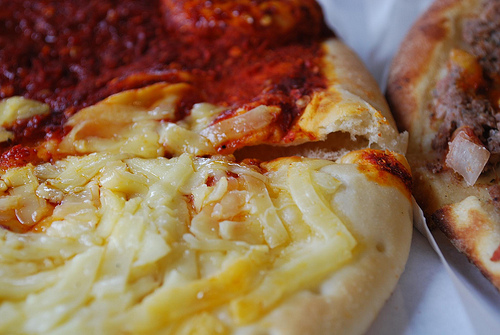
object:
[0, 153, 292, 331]
cheesy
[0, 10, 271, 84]
sauce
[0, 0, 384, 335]
pizza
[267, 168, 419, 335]
good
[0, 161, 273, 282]
onions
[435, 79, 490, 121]
meat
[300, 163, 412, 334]
crust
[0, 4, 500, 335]
scene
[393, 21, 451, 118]
bread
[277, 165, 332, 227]
close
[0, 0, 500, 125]
background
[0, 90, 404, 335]
food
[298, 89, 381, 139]
bread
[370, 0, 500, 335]
another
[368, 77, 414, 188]
edge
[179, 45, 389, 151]
part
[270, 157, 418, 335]
outer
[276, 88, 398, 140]
doughy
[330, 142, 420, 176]
crispy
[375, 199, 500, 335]
cloth